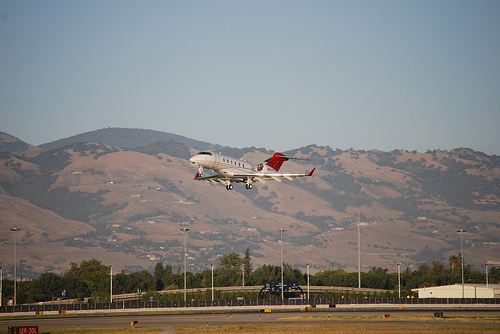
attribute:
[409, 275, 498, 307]
home — small, white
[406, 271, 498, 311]
hangar — small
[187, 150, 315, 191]
airplane — white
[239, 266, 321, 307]
sign — blue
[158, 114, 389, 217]
airplane — white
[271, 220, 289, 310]
light pole — tall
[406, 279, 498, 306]
structure — white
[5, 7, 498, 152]
sky — blue, gray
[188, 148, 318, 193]
plane — white, red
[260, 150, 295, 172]
tail — red